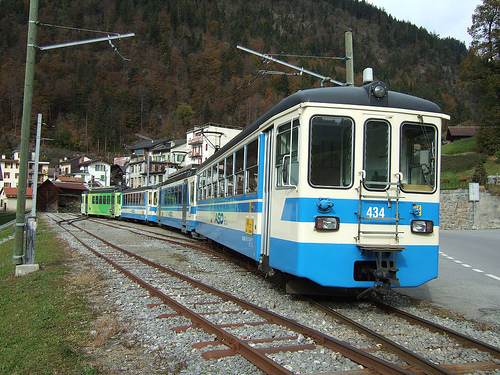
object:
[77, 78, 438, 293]
train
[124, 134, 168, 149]
roof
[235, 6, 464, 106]
mountains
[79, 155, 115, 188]
houses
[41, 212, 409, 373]
train tracks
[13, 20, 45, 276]
post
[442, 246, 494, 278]
lines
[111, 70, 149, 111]
trees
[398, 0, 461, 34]
sky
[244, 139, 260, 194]
windows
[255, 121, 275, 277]
doors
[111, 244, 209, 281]
gravels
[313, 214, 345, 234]
lights